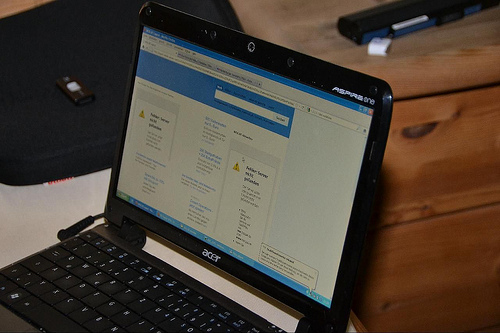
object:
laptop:
[0, 0, 395, 333]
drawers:
[232, 0, 499, 333]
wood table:
[230, 0, 500, 333]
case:
[0, 0, 247, 187]